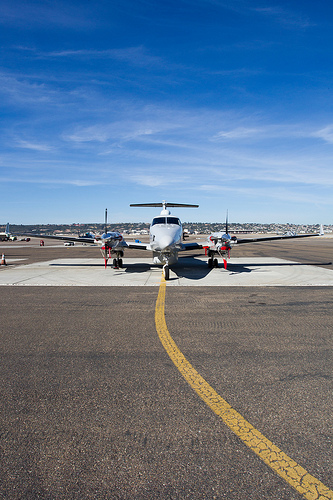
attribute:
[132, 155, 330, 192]
clouds — whispy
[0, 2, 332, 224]
sky — blue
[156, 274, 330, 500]
line — yellow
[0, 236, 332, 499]
ground — grey, cement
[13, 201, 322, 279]
plane — white, grounded, jet, reddish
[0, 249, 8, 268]
cone — orange